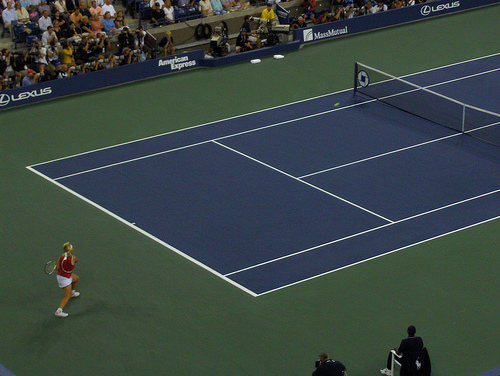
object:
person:
[0, 0, 419, 88]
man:
[380, 325, 424, 375]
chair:
[390, 349, 404, 372]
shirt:
[56, 255, 75, 279]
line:
[150, 104, 353, 279]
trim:
[4, 1, 500, 373]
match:
[25, 57, 500, 301]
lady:
[54, 241, 79, 317]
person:
[311, 352, 346, 376]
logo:
[421, 2, 460, 16]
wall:
[293, 0, 485, 43]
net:
[46, 264, 54, 273]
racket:
[40, 260, 60, 276]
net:
[355, 61, 499, 147]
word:
[0, 87, 52, 107]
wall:
[0, 49, 204, 109]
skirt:
[56, 275, 72, 288]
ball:
[334, 101, 339, 107]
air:
[271, 70, 403, 142]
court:
[0, 5, 500, 376]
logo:
[357, 70, 369, 87]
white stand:
[386, 352, 427, 372]